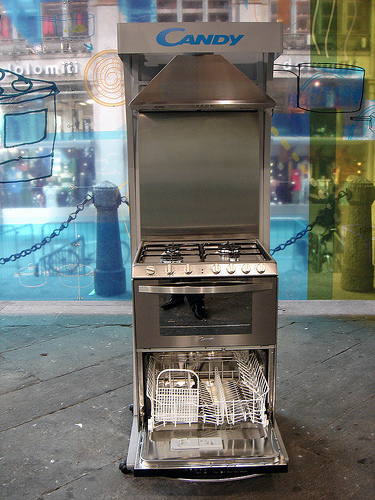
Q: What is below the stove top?
A: Oven.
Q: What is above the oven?
A: Stove top.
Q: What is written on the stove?
A: Candy.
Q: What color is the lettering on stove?
A: Blue.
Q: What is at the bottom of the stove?
A: Dishwasher.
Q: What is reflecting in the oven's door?
A: Shoes.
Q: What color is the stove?
A: Silver.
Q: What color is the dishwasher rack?
A: White.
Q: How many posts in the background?
A: Two.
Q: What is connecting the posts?
A: Chain.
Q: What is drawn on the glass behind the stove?
A: Stove and pot.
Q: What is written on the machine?
A: Candy.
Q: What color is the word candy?
A: Blue.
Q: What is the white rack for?
A: Dishes.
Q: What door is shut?
A: Oven.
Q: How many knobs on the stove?
A: 7.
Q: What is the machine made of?
A: Metal.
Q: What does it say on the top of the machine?
A: Candy.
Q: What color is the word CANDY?
A: Blue.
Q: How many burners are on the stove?
A: Four.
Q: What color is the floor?
A: Gray.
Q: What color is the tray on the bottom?
A: White.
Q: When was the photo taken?
A: In the daytime.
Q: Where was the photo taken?
A: On the street.